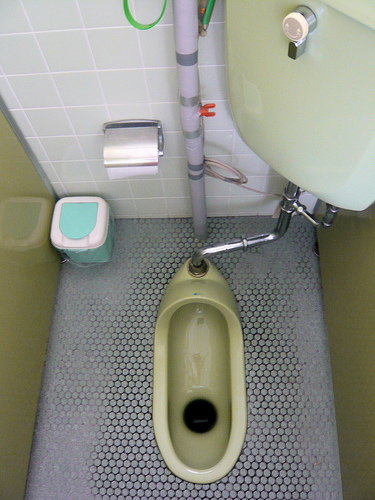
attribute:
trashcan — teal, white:
[48, 191, 123, 275]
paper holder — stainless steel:
[105, 121, 162, 182]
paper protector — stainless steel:
[103, 123, 157, 162]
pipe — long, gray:
[170, 0, 209, 240]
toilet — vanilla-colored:
[145, 252, 270, 494]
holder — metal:
[97, 116, 166, 169]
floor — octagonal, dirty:
[21, 210, 346, 498]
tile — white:
[20, 3, 91, 34]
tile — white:
[84, 25, 145, 78]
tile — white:
[51, 158, 96, 189]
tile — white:
[20, 100, 80, 149]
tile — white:
[94, 64, 157, 113]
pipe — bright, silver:
[187, 187, 294, 264]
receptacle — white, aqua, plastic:
[49, 194, 117, 268]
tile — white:
[124, 177, 170, 203]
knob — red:
[198, 103, 214, 118]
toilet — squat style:
[156, 261, 252, 482]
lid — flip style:
[49, 195, 107, 249]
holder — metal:
[105, 123, 161, 168]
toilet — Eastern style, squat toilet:
[153, 252, 247, 483]